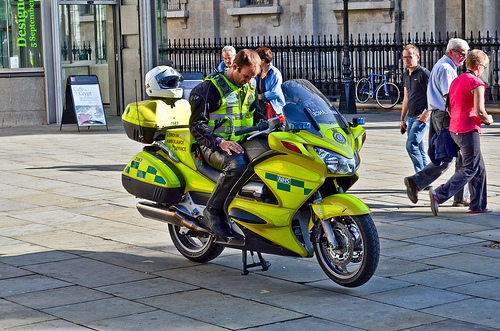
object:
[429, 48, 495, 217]
woman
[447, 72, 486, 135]
shirt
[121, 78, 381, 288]
motorcycle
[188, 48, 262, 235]
man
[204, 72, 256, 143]
vest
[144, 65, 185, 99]
helmet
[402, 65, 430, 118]
shirt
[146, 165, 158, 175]
rectangle design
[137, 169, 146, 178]
rectangle design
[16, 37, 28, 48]
letters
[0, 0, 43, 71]
window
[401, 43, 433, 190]
man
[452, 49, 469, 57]
sunglasses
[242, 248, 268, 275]
stand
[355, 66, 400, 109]
bike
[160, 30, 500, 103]
gate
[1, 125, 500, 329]
walkway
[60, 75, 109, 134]
sign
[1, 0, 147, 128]
store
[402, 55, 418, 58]
glasses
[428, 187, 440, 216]
shoe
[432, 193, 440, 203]
stripes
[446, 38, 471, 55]
hair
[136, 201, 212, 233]
muffler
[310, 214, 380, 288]
front wheel